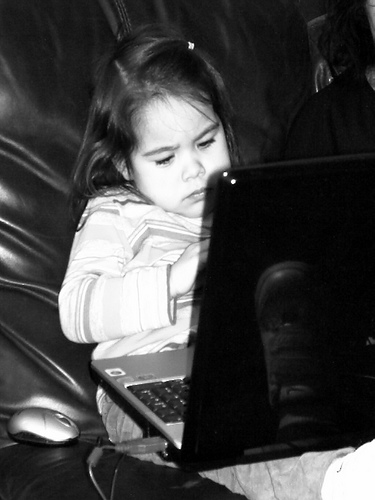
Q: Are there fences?
A: No, there are no fences.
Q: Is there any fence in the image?
A: No, there are no fences.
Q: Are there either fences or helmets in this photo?
A: No, there are no fences or helmets.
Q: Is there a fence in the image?
A: No, there are no fences.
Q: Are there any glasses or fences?
A: No, there are no fences or glasses.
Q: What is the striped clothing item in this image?
A: The clothing item is a shirt.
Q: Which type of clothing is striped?
A: The clothing is a shirt.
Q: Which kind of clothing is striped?
A: The clothing is a shirt.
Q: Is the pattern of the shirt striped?
A: Yes, the shirt is striped.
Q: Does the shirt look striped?
A: Yes, the shirt is striped.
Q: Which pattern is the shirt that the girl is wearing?
A: The shirt is striped.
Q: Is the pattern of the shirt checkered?
A: No, the shirt is striped.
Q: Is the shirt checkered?
A: No, the shirt is striped.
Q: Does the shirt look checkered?
A: No, the shirt is striped.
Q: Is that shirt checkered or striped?
A: The shirt is striped.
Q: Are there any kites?
A: No, there are no kites.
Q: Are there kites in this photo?
A: No, there are no kites.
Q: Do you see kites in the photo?
A: No, there are no kites.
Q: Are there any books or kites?
A: No, there are no kites or books.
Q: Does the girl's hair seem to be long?
A: Yes, the hair is long.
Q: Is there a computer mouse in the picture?
A: Yes, there is a computer mouse.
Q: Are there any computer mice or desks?
A: Yes, there is a computer mouse.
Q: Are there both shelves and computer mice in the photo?
A: No, there is a computer mouse but no shelves.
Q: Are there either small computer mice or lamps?
A: Yes, there is a small computer mouse.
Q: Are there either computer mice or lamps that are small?
A: Yes, the computer mouse is small.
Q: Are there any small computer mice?
A: Yes, there is a small computer mouse.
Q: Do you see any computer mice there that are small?
A: Yes, there is a computer mouse that is small.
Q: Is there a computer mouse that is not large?
A: Yes, there is a small computer mouse.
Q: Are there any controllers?
A: No, there are no controllers.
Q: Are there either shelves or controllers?
A: No, there are no controllers or shelves.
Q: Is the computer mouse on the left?
A: Yes, the computer mouse is on the left of the image.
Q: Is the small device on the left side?
A: Yes, the computer mouse is on the left of the image.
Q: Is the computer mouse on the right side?
A: No, the computer mouse is on the left of the image.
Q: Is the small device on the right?
A: No, the computer mouse is on the left of the image.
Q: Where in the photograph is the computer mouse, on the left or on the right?
A: The computer mouse is on the left of the image.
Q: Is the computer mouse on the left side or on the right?
A: The computer mouse is on the left of the image.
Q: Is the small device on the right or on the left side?
A: The computer mouse is on the left of the image.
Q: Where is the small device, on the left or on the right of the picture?
A: The computer mouse is on the left of the image.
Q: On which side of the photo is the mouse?
A: The mouse is on the left of the image.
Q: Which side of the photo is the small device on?
A: The mouse is on the left of the image.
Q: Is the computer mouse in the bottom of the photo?
A: Yes, the computer mouse is in the bottom of the image.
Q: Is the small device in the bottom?
A: Yes, the computer mouse is in the bottom of the image.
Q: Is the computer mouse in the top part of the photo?
A: No, the computer mouse is in the bottom of the image.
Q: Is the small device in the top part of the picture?
A: No, the computer mouse is in the bottom of the image.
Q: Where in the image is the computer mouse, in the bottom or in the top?
A: The computer mouse is in the bottom of the image.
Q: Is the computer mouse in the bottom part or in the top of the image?
A: The computer mouse is in the bottom of the image.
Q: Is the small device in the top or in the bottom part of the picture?
A: The computer mouse is in the bottom of the image.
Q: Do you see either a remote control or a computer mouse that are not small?
A: No, there is a computer mouse but it is small.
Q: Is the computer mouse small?
A: Yes, the computer mouse is small.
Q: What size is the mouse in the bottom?
A: The mouse is small.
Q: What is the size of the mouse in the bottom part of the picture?
A: The mouse is small.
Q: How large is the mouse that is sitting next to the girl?
A: The computer mouse is small.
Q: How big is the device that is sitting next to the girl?
A: The computer mouse is small.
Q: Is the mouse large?
A: No, the mouse is small.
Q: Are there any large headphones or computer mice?
A: No, there is a computer mouse but it is small.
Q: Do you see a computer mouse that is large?
A: No, there is a computer mouse but it is small.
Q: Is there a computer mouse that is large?
A: No, there is a computer mouse but it is small.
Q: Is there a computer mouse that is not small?
A: No, there is a computer mouse but it is small.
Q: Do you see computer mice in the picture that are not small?
A: No, there is a computer mouse but it is small.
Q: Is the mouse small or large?
A: The mouse is small.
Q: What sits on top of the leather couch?
A: The mouse sits on top of the couch.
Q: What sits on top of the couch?
A: The mouse sits on top of the couch.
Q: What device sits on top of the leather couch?
A: The device is a computer mouse.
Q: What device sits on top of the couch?
A: The device is a computer mouse.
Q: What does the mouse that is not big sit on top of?
A: The mouse sits on top of the couch.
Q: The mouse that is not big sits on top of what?
A: The mouse sits on top of the couch.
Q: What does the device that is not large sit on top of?
A: The mouse sits on top of the couch.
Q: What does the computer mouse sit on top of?
A: The mouse sits on top of the couch.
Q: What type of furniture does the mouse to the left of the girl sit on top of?
A: The mouse sits on top of the couch.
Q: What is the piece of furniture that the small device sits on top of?
A: The piece of furniture is a couch.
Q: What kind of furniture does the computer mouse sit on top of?
A: The mouse sits on top of the couch.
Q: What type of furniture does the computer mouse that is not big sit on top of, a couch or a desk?
A: The mouse sits on top of a couch.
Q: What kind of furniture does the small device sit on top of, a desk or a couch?
A: The mouse sits on top of a couch.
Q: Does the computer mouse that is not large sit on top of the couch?
A: Yes, the mouse sits on top of the couch.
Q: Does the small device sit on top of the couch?
A: Yes, the mouse sits on top of the couch.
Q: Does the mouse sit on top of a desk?
A: No, the mouse sits on top of the couch.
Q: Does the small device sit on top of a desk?
A: No, the mouse sits on top of the couch.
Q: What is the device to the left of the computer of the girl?
A: The device is a computer mouse.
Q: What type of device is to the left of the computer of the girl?
A: The device is a computer mouse.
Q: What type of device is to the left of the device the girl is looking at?
A: The device is a computer mouse.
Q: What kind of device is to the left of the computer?
A: The device is a computer mouse.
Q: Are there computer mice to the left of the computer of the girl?
A: Yes, there is a computer mouse to the left of the computer.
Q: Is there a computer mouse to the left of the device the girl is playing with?
A: Yes, there is a computer mouse to the left of the computer.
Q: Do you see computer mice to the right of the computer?
A: No, the computer mouse is to the left of the computer.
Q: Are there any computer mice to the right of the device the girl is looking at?
A: No, the computer mouse is to the left of the computer.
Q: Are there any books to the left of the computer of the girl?
A: No, there is a computer mouse to the left of the computer.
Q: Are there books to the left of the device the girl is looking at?
A: No, there is a computer mouse to the left of the computer.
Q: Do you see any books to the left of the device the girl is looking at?
A: No, there is a computer mouse to the left of the computer.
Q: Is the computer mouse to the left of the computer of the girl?
A: Yes, the computer mouse is to the left of the computer.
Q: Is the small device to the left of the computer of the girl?
A: Yes, the computer mouse is to the left of the computer.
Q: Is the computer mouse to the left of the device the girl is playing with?
A: Yes, the computer mouse is to the left of the computer.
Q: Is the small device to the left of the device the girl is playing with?
A: Yes, the computer mouse is to the left of the computer.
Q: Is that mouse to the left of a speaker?
A: No, the mouse is to the left of the computer.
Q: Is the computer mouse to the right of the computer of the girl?
A: No, the computer mouse is to the left of the computer.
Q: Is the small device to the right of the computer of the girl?
A: No, the computer mouse is to the left of the computer.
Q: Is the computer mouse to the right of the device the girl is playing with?
A: No, the computer mouse is to the left of the computer.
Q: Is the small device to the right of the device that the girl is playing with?
A: No, the computer mouse is to the left of the computer.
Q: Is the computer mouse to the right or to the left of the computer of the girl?
A: The computer mouse is to the left of the computer.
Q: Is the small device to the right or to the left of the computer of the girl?
A: The computer mouse is to the left of the computer.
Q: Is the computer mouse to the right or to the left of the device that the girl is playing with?
A: The computer mouse is to the left of the computer.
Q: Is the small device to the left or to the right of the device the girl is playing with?
A: The computer mouse is to the left of the computer.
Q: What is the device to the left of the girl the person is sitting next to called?
A: The device is a computer mouse.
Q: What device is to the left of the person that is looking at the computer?
A: The device is a computer mouse.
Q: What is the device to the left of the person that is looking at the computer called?
A: The device is a computer mouse.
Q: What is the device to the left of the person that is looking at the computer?
A: The device is a computer mouse.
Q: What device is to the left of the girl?
A: The device is a computer mouse.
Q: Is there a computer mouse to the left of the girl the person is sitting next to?
A: Yes, there is a computer mouse to the left of the girl.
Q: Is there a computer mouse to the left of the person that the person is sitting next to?
A: Yes, there is a computer mouse to the left of the girl.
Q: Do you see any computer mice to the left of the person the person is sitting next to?
A: Yes, there is a computer mouse to the left of the girl.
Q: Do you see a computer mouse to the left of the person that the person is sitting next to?
A: Yes, there is a computer mouse to the left of the girl.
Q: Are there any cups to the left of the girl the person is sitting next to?
A: No, there is a computer mouse to the left of the girl.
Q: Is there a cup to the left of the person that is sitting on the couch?
A: No, there is a computer mouse to the left of the girl.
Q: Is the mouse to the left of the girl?
A: Yes, the mouse is to the left of the girl.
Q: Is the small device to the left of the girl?
A: Yes, the mouse is to the left of the girl.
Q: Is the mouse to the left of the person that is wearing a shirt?
A: Yes, the mouse is to the left of the girl.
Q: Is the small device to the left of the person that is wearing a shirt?
A: Yes, the mouse is to the left of the girl.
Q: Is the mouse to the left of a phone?
A: No, the mouse is to the left of the girl.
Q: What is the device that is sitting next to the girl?
A: The device is a computer mouse.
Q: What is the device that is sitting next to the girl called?
A: The device is a computer mouse.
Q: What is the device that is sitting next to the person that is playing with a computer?
A: The device is a computer mouse.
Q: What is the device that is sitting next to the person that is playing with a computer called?
A: The device is a computer mouse.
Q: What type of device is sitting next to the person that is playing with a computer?
A: The device is a computer mouse.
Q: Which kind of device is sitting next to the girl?
A: The device is a computer mouse.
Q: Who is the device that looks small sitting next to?
A: The computer mouse is sitting next to the girl.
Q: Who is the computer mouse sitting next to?
A: The computer mouse is sitting next to the girl.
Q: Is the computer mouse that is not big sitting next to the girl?
A: Yes, the mouse is sitting next to the girl.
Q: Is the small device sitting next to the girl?
A: Yes, the mouse is sitting next to the girl.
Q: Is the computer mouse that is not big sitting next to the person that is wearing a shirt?
A: Yes, the mouse is sitting next to the girl.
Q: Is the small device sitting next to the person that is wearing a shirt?
A: Yes, the mouse is sitting next to the girl.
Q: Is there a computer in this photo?
A: Yes, there is a computer.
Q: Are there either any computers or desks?
A: Yes, there is a computer.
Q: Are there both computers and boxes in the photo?
A: No, there is a computer but no boxes.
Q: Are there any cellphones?
A: No, there are no cellphones.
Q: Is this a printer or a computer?
A: This is a computer.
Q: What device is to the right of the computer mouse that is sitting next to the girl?
A: The device is a computer.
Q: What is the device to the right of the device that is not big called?
A: The device is a computer.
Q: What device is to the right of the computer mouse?
A: The device is a computer.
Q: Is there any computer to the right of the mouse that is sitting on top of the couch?
A: Yes, there is a computer to the right of the computer mouse.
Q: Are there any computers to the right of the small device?
A: Yes, there is a computer to the right of the computer mouse.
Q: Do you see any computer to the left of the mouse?
A: No, the computer is to the right of the mouse.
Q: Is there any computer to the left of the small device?
A: No, the computer is to the right of the mouse.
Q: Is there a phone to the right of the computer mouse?
A: No, there is a computer to the right of the computer mouse.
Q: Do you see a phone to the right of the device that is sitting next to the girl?
A: No, there is a computer to the right of the computer mouse.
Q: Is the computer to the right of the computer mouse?
A: Yes, the computer is to the right of the computer mouse.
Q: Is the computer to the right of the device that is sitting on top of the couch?
A: Yes, the computer is to the right of the computer mouse.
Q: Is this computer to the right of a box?
A: No, the computer is to the right of the computer mouse.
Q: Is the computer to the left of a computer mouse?
A: No, the computer is to the right of a computer mouse.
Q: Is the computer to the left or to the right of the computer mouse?
A: The computer is to the right of the computer mouse.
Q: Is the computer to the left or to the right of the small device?
A: The computer is to the right of the computer mouse.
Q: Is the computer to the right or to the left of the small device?
A: The computer is to the right of the computer mouse.